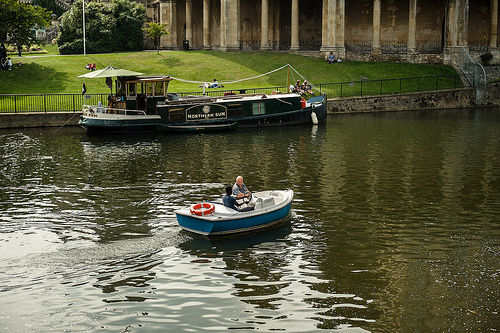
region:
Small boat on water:
[171, 166, 301, 241]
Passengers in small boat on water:
[218, 172, 259, 211]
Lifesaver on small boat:
[190, 200, 215, 222]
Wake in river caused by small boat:
[44, 228, 191, 264]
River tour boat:
[75, 64, 332, 136]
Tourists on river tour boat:
[285, 70, 317, 105]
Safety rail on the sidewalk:
[10, 90, 76, 112]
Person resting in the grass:
[322, 48, 337, 66]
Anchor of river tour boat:
[46, 108, 84, 134]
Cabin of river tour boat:
[112, 76, 174, 106]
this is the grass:
[172, 55, 229, 77]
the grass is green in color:
[176, 56, 243, 71]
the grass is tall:
[28, 59, 63, 94]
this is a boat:
[163, 173, 304, 230]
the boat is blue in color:
[184, 217, 204, 227]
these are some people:
[225, 170, 249, 210]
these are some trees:
[2, 0, 145, 50]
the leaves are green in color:
[3, 2, 40, 32]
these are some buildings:
[221, 3, 493, 51]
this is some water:
[365, 115, 487, 270]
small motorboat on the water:
[160, 166, 309, 245]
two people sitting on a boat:
[221, 171, 254, 213]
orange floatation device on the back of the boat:
[188, 196, 216, 221]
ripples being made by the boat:
[56, 226, 188, 260]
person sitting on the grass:
[324, 48, 341, 63]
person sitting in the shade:
[2, 54, 19, 72]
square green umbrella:
[80, 63, 142, 85]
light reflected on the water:
[157, 256, 232, 332]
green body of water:
[3, 105, 497, 332]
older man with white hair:
[233, 173, 253, 197]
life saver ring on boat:
[187, 200, 215, 219]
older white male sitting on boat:
[233, 176, 250, 206]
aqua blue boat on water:
[169, 174, 297, 241]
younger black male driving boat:
[220, 185, 255, 216]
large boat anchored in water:
[75, 65, 328, 135]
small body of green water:
[6, 104, 494, 331]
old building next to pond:
[144, 0, 495, 65]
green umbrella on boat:
[79, 62, 139, 82]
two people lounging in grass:
[289, 77, 311, 97]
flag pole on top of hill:
[79, 2, 91, 55]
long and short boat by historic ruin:
[42, 5, 397, 272]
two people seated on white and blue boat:
[176, 155, 301, 240]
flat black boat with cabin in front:
[65, 55, 340, 161]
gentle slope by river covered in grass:
[10, 20, 460, 116]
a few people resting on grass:
[5, 32, 352, 87]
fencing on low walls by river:
[5, 36, 485, 121]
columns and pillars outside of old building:
[171, 0, 471, 56]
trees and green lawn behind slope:
[7, 5, 157, 56]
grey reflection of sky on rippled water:
[10, 150, 321, 310]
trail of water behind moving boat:
[10, 221, 191, 267]